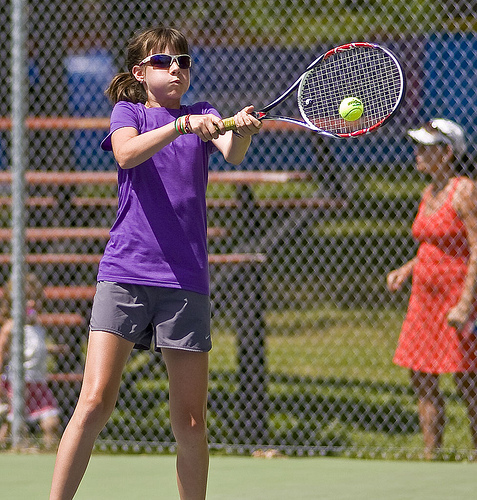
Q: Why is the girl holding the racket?
A: She is preparing to hit the ball.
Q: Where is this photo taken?
A: On a tennis court.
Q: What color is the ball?
A: Green.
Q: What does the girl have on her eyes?
A: Sunglasses.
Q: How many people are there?
A: Three.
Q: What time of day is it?
A: Daytime.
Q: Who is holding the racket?
A: A girl.